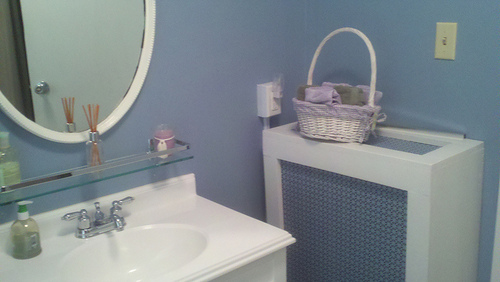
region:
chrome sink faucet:
[55, 187, 152, 261]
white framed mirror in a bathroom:
[0, 0, 160, 167]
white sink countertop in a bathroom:
[1, 165, 282, 275]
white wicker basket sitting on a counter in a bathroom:
[292, 14, 399, 164]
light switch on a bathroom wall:
[418, 10, 466, 80]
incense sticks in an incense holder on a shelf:
[72, 88, 127, 190]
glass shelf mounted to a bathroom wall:
[1, 110, 209, 208]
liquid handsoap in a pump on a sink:
[6, 192, 66, 269]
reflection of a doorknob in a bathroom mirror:
[6, 3, 172, 149]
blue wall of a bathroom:
[191, 25, 259, 108]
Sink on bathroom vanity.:
[65, 219, 227, 280]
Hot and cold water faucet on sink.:
[56, 193, 151, 240]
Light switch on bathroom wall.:
[424, 18, 461, 63]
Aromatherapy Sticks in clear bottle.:
[75, 100, 112, 169]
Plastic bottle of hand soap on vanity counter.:
[0, 198, 51, 261]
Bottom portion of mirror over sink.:
[6, 20, 171, 153]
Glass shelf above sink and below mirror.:
[1, 140, 217, 202]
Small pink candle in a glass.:
[144, 118, 183, 160]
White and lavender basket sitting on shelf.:
[297, 15, 397, 148]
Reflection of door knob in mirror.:
[27, 70, 52, 97]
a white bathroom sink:
[2, 170, 287, 278]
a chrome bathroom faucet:
[60, 193, 133, 238]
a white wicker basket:
[298, 19, 383, 145]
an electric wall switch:
[428, 17, 461, 65]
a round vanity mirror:
[0, 3, 160, 148]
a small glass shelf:
[0, 136, 201, 213]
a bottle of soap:
[5, 196, 46, 264]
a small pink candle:
[148, 122, 175, 159]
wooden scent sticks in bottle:
[78, 101, 108, 172]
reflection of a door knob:
[31, 77, 50, 102]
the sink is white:
[81, 207, 176, 271]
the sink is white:
[76, 134, 250, 276]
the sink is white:
[151, 159, 236, 241]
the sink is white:
[141, 196, 247, 265]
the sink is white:
[159, 179, 274, 279]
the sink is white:
[134, 216, 201, 276]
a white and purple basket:
[257, 14, 419, 178]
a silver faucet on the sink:
[40, 183, 151, 246]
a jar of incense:
[67, 83, 112, 203]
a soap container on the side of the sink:
[2, 185, 54, 265]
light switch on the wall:
[420, 18, 463, 76]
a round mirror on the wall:
[0, 0, 165, 165]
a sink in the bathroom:
[0, 158, 325, 274]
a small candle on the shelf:
[148, 113, 193, 195]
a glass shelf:
[8, 107, 215, 227]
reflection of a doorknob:
[19, 71, 78, 111]